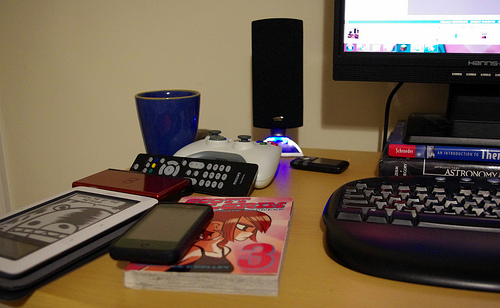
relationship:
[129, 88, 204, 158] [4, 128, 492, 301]
coffee cup sitting on desk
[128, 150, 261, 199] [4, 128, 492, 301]
remote control on desk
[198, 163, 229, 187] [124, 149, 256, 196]
buttons are on remote control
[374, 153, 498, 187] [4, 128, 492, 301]
book on desk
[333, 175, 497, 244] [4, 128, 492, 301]
keyboard sitting on desk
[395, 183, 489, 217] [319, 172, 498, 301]
keys are on keyboard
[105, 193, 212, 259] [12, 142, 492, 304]
cell phone laying on desk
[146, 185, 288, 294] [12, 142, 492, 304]
book laying on desk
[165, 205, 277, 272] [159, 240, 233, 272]
girl in tank top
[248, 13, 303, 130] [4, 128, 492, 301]
speaker on desk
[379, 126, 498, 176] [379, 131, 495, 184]
stack of books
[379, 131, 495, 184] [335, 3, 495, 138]
books under monitor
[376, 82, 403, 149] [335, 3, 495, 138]
wiring attached to monitor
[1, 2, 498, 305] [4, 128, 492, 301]
items on desk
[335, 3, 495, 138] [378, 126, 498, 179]
monitor resting on stack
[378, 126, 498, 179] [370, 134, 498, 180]
stack of books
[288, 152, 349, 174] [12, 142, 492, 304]
cellphone on desk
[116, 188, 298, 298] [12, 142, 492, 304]
book on desk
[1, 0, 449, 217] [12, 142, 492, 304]
wall behind desk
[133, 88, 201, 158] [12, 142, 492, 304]
coffee cup on desk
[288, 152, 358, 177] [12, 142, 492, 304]
cellphone laying on desk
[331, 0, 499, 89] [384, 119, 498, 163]
monitor sitting on book